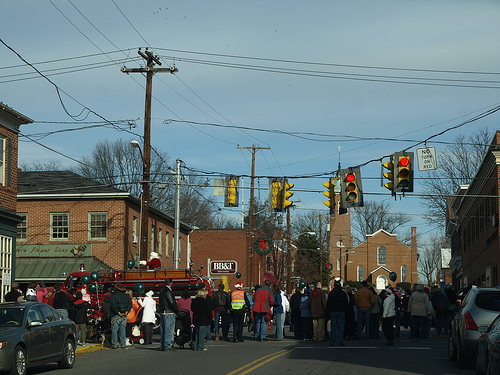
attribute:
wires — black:
[158, 166, 499, 202]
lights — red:
[340, 169, 365, 211]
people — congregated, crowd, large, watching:
[19, 281, 436, 350]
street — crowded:
[21, 329, 459, 371]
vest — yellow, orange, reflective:
[231, 290, 247, 309]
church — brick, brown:
[314, 145, 420, 288]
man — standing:
[104, 281, 134, 350]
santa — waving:
[138, 248, 163, 273]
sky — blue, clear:
[4, 6, 496, 184]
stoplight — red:
[392, 153, 414, 192]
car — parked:
[1, 298, 85, 375]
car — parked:
[447, 281, 495, 365]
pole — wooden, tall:
[239, 148, 267, 316]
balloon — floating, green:
[387, 268, 401, 284]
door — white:
[373, 274, 388, 296]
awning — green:
[17, 245, 110, 285]